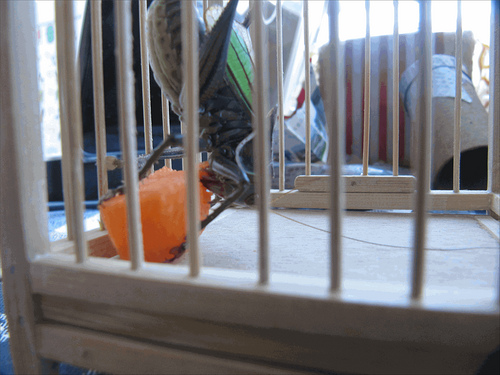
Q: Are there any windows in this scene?
A: Yes, there is a window.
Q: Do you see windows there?
A: Yes, there is a window.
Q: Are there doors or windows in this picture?
A: Yes, there is a window.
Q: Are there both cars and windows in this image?
A: No, there is a window but no cars.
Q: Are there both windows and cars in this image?
A: No, there is a window but no cars.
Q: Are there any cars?
A: No, there are no cars.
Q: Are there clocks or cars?
A: No, there are no cars or clocks.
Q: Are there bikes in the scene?
A: No, there are no bikes.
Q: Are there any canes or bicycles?
A: No, there are no bicycles or canes.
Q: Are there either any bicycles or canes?
A: No, there are no bicycles or canes.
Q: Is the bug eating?
A: Yes, the bug is eating.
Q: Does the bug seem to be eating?
A: Yes, the bug is eating.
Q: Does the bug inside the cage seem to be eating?
A: Yes, the bug is eating.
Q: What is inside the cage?
A: The bug is inside the cage.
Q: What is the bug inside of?
A: The bug is inside the cage.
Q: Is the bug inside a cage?
A: Yes, the bug is inside a cage.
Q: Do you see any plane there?
A: No, there are no airplanes.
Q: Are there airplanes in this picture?
A: No, there are no airplanes.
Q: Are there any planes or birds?
A: No, there are no planes or birds.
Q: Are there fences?
A: No, there are no fences.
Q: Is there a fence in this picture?
A: No, there are no fences.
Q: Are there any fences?
A: No, there are no fences.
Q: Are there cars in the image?
A: No, there are no cars.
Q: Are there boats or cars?
A: No, there are no cars or boats.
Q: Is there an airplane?
A: No, there are no airplanes.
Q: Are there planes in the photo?
A: No, there are no planes.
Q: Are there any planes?
A: No, there are no planes.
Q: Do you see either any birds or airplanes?
A: No, there are no airplanes or birds.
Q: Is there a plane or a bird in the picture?
A: No, there are no airplanes or birds.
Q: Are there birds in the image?
A: No, there are no birds.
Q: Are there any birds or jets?
A: No, there are no birds or jets.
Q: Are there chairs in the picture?
A: Yes, there is a chair.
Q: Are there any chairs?
A: Yes, there is a chair.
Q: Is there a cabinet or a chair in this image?
A: Yes, there is a chair.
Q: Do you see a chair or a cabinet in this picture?
A: Yes, there is a chair.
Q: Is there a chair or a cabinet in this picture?
A: Yes, there is a chair.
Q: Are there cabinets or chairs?
A: Yes, there is a chair.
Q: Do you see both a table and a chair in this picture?
A: No, there is a chair but no tables.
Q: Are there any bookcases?
A: No, there are no bookcases.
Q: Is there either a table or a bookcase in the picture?
A: No, there are no bookcases or tables.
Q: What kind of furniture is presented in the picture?
A: The furniture is a chair.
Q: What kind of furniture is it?
A: The piece of furniture is a chair.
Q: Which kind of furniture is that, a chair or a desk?
A: That is a chair.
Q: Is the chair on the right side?
A: Yes, the chair is on the right of the image.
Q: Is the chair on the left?
A: No, the chair is on the right of the image.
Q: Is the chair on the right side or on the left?
A: The chair is on the right of the image.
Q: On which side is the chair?
A: The chair is on the right of the image.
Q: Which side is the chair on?
A: The chair is on the right of the image.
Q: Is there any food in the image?
A: Yes, there is food.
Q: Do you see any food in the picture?
A: Yes, there is food.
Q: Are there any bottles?
A: No, there are no bottles.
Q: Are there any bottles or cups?
A: No, there are no bottles or cups.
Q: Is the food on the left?
A: Yes, the food is on the left of the image.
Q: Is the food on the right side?
A: No, the food is on the left of the image.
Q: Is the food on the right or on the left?
A: The food is on the left of the image.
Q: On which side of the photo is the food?
A: The food is on the left of the image.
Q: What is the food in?
A: The food is in the cage.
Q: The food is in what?
A: The food is in the cage.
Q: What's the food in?
A: The food is in the cage.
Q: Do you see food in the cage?
A: Yes, there is food in the cage.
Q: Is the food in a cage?
A: Yes, the food is in a cage.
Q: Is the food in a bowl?
A: No, the food is in a cage.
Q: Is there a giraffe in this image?
A: No, there are no giraffes.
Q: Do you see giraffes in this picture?
A: No, there are no giraffes.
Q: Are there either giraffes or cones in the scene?
A: No, there are no giraffes or cones.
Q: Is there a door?
A: Yes, there is a door.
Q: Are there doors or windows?
A: Yes, there is a door.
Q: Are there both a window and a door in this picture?
A: Yes, there are both a door and a window.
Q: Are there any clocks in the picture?
A: No, there are no clocks.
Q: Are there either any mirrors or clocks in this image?
A: No, there are no clocks or mirrors.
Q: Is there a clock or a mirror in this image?
A: No, there are no clocks or mirrors.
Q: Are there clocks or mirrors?
A: No, there are no clocks or mirrors.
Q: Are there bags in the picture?
A: No, there are no bags.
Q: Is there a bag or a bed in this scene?
A: No, there are no bags or beds.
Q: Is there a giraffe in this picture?
A: No, there are no giraffes.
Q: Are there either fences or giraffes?
A: No, there are no giraffes or fences.